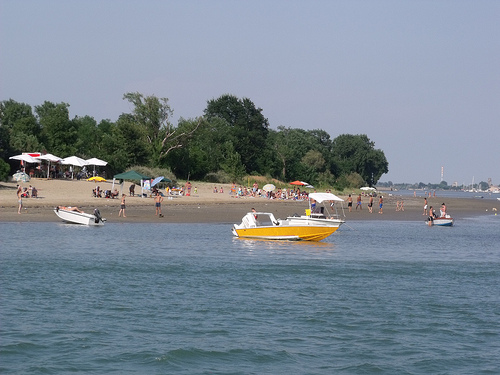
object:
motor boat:
[230, 208, 345, 243]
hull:
[236, 228, 337, 242]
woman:
[55, 205, 84, 213]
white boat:
[52, 205, 106, 225]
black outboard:
[94, 208, 106, 224]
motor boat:
[425, 213, 453, 225]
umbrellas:
[8, 153, 42, 163]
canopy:
[111, 171, 152, 196]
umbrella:
[290, 180, 304, 185]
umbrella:
[87, 176, 106, 182]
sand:
[186, 198, 233, 221]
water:
[0, 189, 500, 374]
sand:
[44, 181, 75, 204]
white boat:
[286, 216, 347, 228]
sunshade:
[309, 192, 347, 220]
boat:
[424, 217, 453, 227]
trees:
[367, 148, 389, 185]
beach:
[0, 193, 499, 221]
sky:
[0, 0, 500, 193]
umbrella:
[151, 176, 164, 186]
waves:
[156, 284, 246, 347]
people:
[112, 189, 118, 198]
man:
[154, 191, 164, 215]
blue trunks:
[156, 203, 162, 206]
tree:
[153, 120, 203, 167]